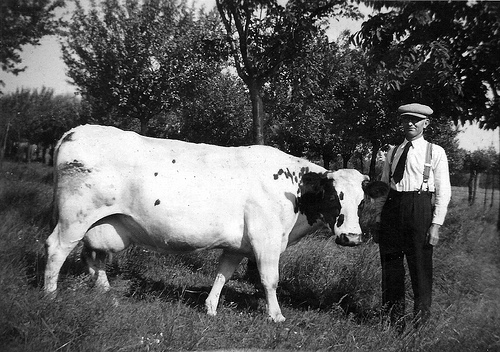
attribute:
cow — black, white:
[43, 124, 390, 323]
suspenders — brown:
[378, 141, 439, 326]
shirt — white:
[379, 137, 452, 227]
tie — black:
[391, 141, 413, 183]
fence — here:
[446, 170, 498, 209]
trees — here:
[0, 1, 498, 189]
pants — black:
[380, 187, 438, 331]